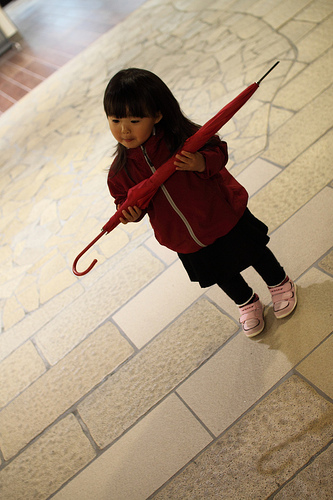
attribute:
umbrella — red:
[71, 60, 280, 280]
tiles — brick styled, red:
[1, 0, 146, 115]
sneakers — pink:
[236, 281, 298, 339]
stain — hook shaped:
[247, 411, 332, 482]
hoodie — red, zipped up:
[106, 125, 250, 255]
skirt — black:
[175, 204, 271, 293]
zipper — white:
[141, 144, 206, 253]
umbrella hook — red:
[64, 226, 108, 279]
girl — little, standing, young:
[101, 62, 300, 345]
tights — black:
[210, 248, 289, 308]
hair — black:
[96, 71, 224, 180]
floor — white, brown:
[1, 1, 331, 500]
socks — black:
[223, 276, 296, 310]